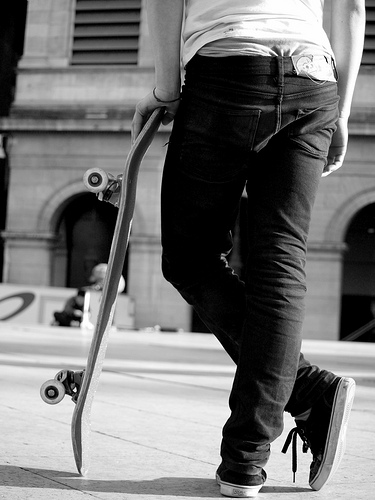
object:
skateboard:
[37, 105, 170, 476]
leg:
[157, 150, 311, 413]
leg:
[214, 141, 328, 495]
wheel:
[85, 165, 108, 194]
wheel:
[41, 375, 67, 405]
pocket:
[179, 94, 262, 188]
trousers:
[156, 52, 340, 473]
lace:
[291, 431, 297, 484]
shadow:
[0, 457, 308, 496]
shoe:
[295, 365, 352, 491]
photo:
[0, 1, 374, 498]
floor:
[0, 329, 374, 498]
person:
[129, 0, 366, 495]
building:
[0, 0, 374, 342]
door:
[51, 190, 129, 292]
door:
[339, 202, 374, 343]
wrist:
[148, 86, 181, 107]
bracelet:
[149, 85, 183, 107]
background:
[0, 0, 374, 498]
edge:
[39, 101, 159, 476]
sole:
[306, 375, 352, 489]